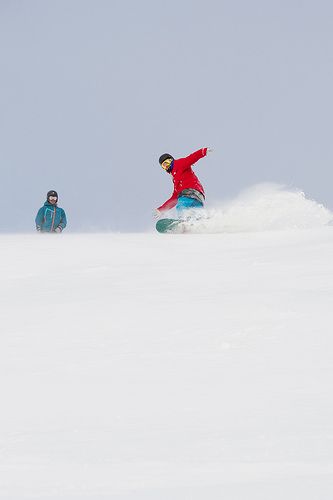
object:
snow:
[4, 197, 328, 499]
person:
[151, 144, 216, 235]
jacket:
[159, 145, 206, 212]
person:
[33, 184, 68, 237]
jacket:
[34, 201, 69, 234]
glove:
[53, 226, 62, 235]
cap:
[158, 152, 173, 166]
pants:
[175, 192, 202, 219]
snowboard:
[154, 215, 205, 234]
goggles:
[161, 158, 173, 170]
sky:
[0, 2, 331, 229]